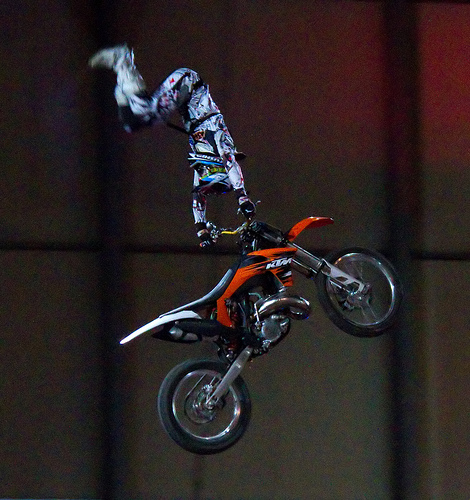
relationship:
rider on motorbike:
[88, 45, 261, 230] [118, 219, 404, 454]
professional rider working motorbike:
[88, 45, 261, 230] [118, 219, 404, 454]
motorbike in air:
[118, 219, 404, 454] [3, 7, 467, 493]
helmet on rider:
[191, 159, 238, 200] [88, 45, 261, 230]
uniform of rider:
[143, 67, 242, 193] [88, 45, 261, 230]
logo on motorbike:
[255, 256, 298, 271] [118, 219, 404, 454]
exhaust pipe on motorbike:
[241, 296, 310, 324] [118, 219, 404, 454]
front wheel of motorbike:
[318, 245, 408, 338] [118, 219, 404, 454]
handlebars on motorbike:
[206, 210, 256, 241] [118, 219, 404, 454]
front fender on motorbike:
[291, 208, 334, 242] [118, 219, 404, 454]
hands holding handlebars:
[191, 199, 262, 248] [206, 210, 256, 241]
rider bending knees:
[88, 45, 261, 230] [111, 98, 165, 137]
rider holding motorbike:
[88, 45, 261, 230] [118, 219, 404, 454]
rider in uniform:
[88, 45, 261, 230] [143, 67, 242, 193]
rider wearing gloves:
[88, 45, 261, 230] [191, 199, 262, 248]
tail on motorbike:
[117, 305, 199, 349] [118, 219, 404, 454]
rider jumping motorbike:
[88, 45, 261, 230] [118, 219, 404, 454]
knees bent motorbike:
[111, 98, 165, 137] [118, 219, 404, 454]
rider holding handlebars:
[88, 45, 261, 230] [206, 210, 256, 241]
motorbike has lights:
[118, 219, 404, 454] [259, 218, 285, 246]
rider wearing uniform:
[88, 45, 261, 230] [143, 67, 242, 193]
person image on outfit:
[197, 129, 222, 167] [143, 67, 242, 193]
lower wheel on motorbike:
[158, 361, 250, 452] [118, 219, 404, 454]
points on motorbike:
[177, 317, 228, 339] [118, 219, 404, 454]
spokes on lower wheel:
[176, 380, 238, 436] [158, 361, 250, 452]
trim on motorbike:
[240, 266, 269, 276] [118, 219, 404, 454]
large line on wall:
[2, 241, 468, 262] [3, 7, 467, 493]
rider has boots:
[88, 45, 261, 230] [87, 42, 143, 110]